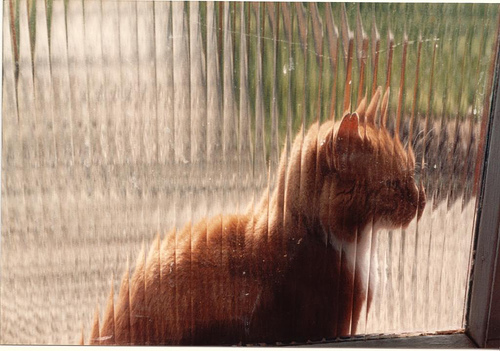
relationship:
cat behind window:
[81, 84, 425, 338] [4, 3, 499, 346]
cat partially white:
[81, 84, 425, 338] [322, 230, 376, 291]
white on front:
[322, 230, 376, 291] [353, 228, 370, 336]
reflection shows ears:
[328, 32, 431, 147] [355, 87, 390, 127]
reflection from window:
[328, 32, 431, 147] [4, 3, 499, 346]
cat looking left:
[81, 84, 425, 338] [461, 5, 483, 350]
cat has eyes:
[81, 84, 425, 338] [385, 179, 402, 190]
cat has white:
[81, 84, 425, 338] [322, 230, 376, 291]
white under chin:
[322, 230, 376, 291] [380, 217, 414, 231]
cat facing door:
[81, 84, 425, 338] [466, 25, 499, 349]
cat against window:
[81, 84, 425, 338] [4, 3, 499, 346]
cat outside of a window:
[81, 84, 425, 338] [4, 3, 499, 346]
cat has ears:
[81, 84, 425, 338] [355, 87, 390, 127]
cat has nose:
[81, 84, 425, 338] [415, 201, 426, 207]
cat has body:
[81, 84, 425, 338] [82, 220, 373, 336]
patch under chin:
[322, 230, 376, 291] [380, 217, 414, 231]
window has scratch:
[4, 3, 499, 346] [184, 19, 444, 61]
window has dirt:
[4, 3, 499, 346] [385, 117, 479, 196]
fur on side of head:
[319, 174, 373, 237] [288, 122, 431, 239]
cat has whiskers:
[81, 84, 425, 338] [384, 204, 414, 230]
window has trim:
[4, 3, 499, 346] [309, 330, 498, 345]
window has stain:
[4, 3, 499, 346] [476, 48, 483, 196]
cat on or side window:
[81, 84, 425, 338] [4, 3, 499, 346]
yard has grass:
[166, 2, 499, 204] [188, 3, 480, 193]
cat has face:
[81, 84, 425, 338] [378, 171, 425, 227]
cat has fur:
[81, 84, 425, 338] [319, 174, 373, 237]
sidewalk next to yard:
[51, 1, 217, 161] [166, 2, 499, 204]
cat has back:
[81, 84, 425, 338] [156, 218, 261, 248]